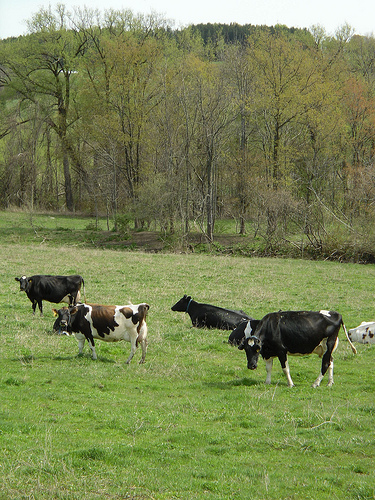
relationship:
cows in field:
[14, 272, 374, 392] [2, 212, 374, 499]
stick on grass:
[40, 233, 50, 244] [2, 212, 374, 499]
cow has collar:
[170, 292, 255, 331] [184, 297, 194, 313]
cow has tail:
[15, 272, 86, 317] [81, 281, 89, 305]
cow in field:
[348, 319, 374, 346] [2, 212, 374, 499]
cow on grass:
[170, 292, 255, 331] [2, 212, 374, 499]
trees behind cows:
[1, 1, 374, 239] [14, 272, 374, 392]